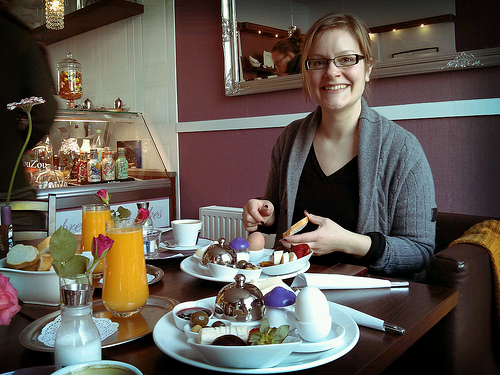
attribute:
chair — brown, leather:
[411, 190, 495, 262]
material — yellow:
[483, 225, 498, 244]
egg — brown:
[293, 286, 329, 319]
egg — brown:
[245, 230, 266, 250]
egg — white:
[295, 284, 331, 323]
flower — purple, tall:
[1, 87, 48, 207]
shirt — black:
[295, 146, 362, 233]